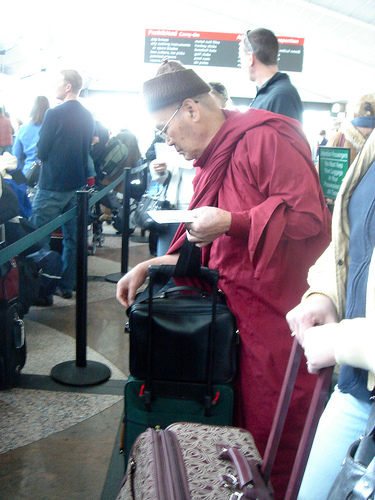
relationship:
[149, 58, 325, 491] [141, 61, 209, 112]
man has hat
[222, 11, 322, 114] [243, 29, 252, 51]
man wearing sunglasses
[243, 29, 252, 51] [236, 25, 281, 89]
sunglasses on head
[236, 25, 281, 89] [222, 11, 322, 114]
head of man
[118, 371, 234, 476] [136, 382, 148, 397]
suitcase on red accent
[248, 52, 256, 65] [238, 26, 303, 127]
ear of man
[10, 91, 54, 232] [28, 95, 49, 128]
person has hair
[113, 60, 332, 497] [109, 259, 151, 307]
man has hand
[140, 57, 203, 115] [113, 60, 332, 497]
hat on man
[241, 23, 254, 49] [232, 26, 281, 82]
sunglasses on head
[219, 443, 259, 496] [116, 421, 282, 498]
handle on suitcase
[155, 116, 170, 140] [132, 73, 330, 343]
glasses on man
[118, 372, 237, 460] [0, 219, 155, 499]
suitcase on ground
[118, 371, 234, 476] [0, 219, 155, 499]
suitcase on ground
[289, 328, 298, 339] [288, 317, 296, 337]
ring on finger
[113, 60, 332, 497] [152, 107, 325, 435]
man in robe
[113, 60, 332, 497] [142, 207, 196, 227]
man holding paper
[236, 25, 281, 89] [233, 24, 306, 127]
head of man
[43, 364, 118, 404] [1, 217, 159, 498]
stripe in tile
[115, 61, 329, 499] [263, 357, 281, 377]
he in red